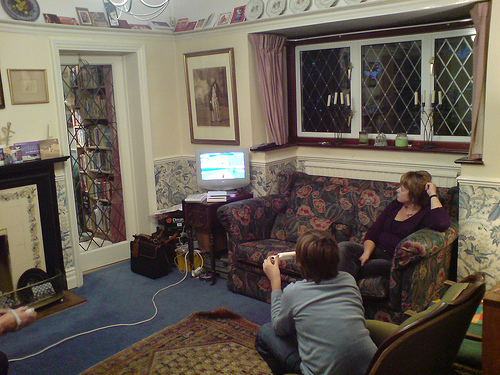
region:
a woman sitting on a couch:
[350, 171, 455, 291]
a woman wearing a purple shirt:
[357, 173, 452, 293]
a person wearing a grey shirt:
[264, 228, 380, 372]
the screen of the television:
[199, 150, 248, 187]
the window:
[294, 43, 474, 141]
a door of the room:
[56, 41, 153, 261]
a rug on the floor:
[86, 303, 264, 373]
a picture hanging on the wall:
[8, 68, 48, 101]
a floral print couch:
[224, 170, 454, 317]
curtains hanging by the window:
[251, 40, 293, 146]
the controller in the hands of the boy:
[265, 241, 299, 270]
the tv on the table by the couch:
[194, 149, 254, 193]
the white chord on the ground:
[135, 251, 212, 318]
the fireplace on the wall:
[0, 160, 74, 305]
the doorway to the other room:
[60, 58, 139, 273]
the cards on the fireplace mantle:
[0, 126, 65, 162]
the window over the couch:
[292, 38, 482, 146]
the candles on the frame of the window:
[355, 126, 419, 149]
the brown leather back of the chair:
[365, 265, 495, 374]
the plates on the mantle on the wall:
[242, 0, 372, 22]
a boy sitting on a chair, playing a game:
[256, 224, 376, 374]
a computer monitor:
[196, 151, 253, 191]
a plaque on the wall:
[7, 68, 51, 105]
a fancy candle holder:
[411, 85, 446, 154]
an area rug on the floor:
[81, 307, 268, 374]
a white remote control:
[274, 250, 296, 265]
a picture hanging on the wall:
[183, 46, 243, 148]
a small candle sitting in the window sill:
[395, 130, 410, 148]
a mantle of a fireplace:
[1, 150, 76, 172]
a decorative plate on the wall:
[244, 2, 264, 19]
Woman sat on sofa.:
[328, 163, 440, 280]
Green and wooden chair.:
[365, 268, 470, 369]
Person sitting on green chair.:
[255, 236, 376, 373]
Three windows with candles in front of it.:
[291, 25, 478, 150]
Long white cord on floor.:
[1, 245, 203, 367]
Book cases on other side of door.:
[67, 65, 122, 240]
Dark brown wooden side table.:
[178, 190, 255, 288]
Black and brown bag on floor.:
[125, 226, 172, 279]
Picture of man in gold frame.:
[175, 47, 242, 146]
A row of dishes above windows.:
[247, 0, 362, 24]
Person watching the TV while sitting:
[251, 228, 382, 374]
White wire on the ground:
[2, 247, 206, 365]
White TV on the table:
[192, 143, 254, 194]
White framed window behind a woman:
[253, 8, 490, 153]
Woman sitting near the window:
[338, 169, 452, 282]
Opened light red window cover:
[248, 30, 293, 148]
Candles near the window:
[322, 91, 354, 146]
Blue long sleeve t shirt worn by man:
[267, 270, 379, 374]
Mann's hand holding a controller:
[260, 251, 284, 276]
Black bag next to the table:
[127, 234, 167, 278]